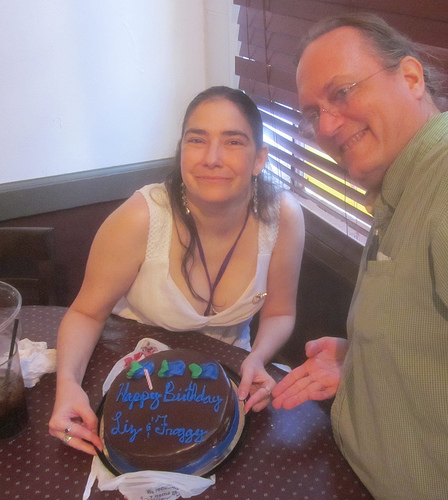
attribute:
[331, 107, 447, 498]
shirt — green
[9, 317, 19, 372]
stirrer — plastic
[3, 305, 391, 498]
tablecloth — brown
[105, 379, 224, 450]
frosting — blue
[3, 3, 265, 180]
wall — white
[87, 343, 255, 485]
cake — chocolate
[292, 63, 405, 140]
glasses — wire rim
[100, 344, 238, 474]
cake — brown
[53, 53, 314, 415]
lady — light skinned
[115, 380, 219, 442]
writing — blue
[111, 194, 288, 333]
shirt — white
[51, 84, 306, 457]
lady — light skinned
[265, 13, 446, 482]
man — light skinned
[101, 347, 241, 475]
birthday cake — brown and blue